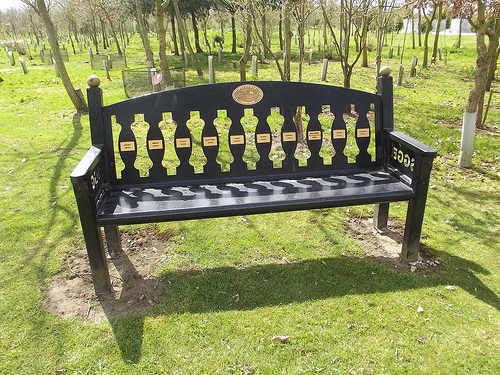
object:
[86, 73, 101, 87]
ball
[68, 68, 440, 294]
bench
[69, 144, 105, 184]
armrest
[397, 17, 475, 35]
fence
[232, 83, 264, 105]
symbol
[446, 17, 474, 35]
buildings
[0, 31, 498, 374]
grass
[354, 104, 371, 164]
plaques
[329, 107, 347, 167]
plaques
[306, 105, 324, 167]
plaques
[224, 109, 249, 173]
plaques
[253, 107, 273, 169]
plaques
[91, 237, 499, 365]
shadow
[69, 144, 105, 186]
arm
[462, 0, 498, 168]
plants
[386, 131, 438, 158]
armrest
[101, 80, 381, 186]
backrest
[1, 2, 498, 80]
background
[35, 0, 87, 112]
tree trunk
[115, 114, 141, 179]
plaque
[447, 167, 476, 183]
brown grass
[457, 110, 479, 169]
white pipe